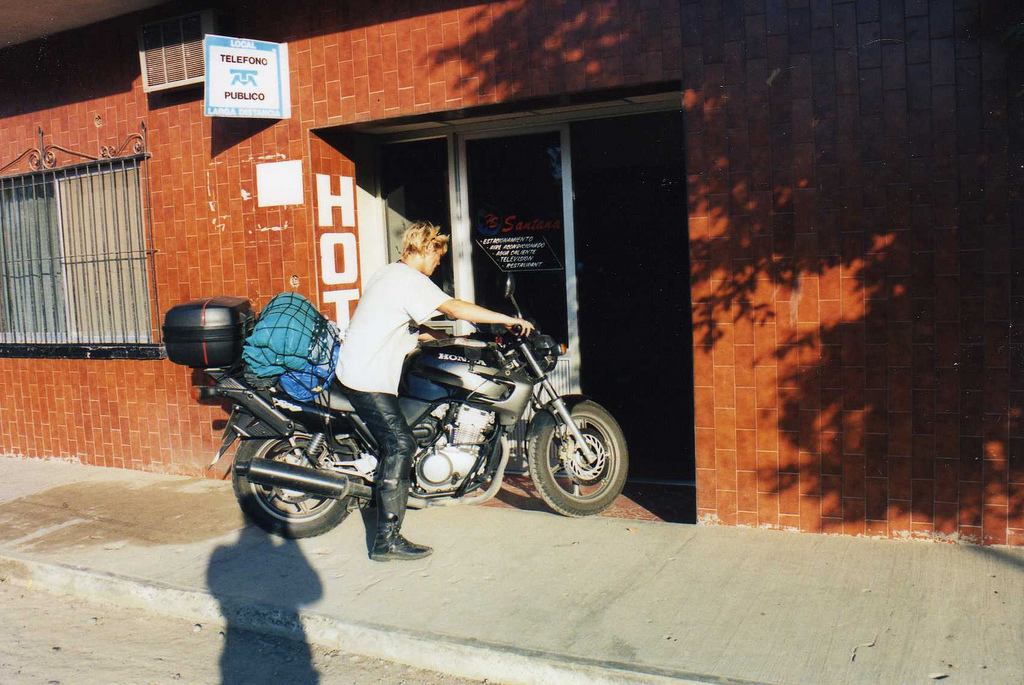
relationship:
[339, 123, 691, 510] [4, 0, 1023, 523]
door way of building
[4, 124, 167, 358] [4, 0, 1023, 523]
window on building